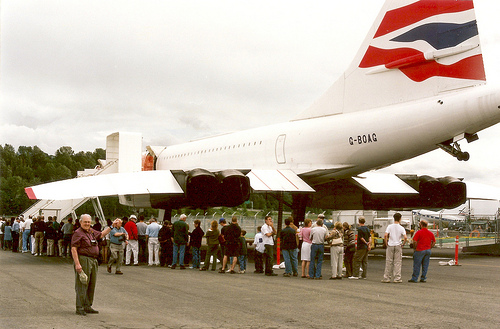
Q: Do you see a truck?
A: No, there are no trucks.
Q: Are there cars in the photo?
A: No, there are no cars.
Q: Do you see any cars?
A: No, there are no cars.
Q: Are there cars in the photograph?
A: No, there are no cars.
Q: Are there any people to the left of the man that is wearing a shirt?
A: Yes, there are people to the left of the man.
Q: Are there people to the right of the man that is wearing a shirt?
A: No, the people are to the left of the man.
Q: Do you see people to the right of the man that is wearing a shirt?
A: No, the people are to the left of the man.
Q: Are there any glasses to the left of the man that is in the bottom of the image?
A: No, there are people to the left of the man.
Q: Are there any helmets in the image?
A: No, there are no helmets.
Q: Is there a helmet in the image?
A: No, there are no helmets.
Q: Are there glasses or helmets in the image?
A: No, there are no helmets or glasses.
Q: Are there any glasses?
A: No, there are no glasses.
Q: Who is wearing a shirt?
A: The man is wearing a shirt.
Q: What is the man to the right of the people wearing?
A: The man is wearing a shirt.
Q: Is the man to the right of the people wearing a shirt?
A: Yes, the man is wearing a shirt.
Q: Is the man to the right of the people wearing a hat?
A: No, the man is wearing a shirt.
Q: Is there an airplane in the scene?
A: Yes, there is an airplane.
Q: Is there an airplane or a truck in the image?
A: Yes, there is an airplane.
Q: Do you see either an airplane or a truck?
A: Yes, there is an airplane.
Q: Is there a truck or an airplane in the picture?
A: Yes, there is an airplane.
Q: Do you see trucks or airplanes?
A: Yes, there is an airplane.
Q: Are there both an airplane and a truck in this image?
A: No, there is an airplane but no trucks.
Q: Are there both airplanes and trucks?
A: No, there is an airplane but no trucks.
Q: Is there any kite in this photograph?
A: No, there are no kites.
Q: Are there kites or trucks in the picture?
A: No, there are no kites or trucks.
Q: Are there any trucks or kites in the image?
A: No, there are no kites or trucks.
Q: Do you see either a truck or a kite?
A: No, there are no kites or trucks.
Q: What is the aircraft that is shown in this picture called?
A: The aircraft is an airplane.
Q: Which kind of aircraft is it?
A: The aircraft is an airplane.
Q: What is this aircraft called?
A: This is an airplane.